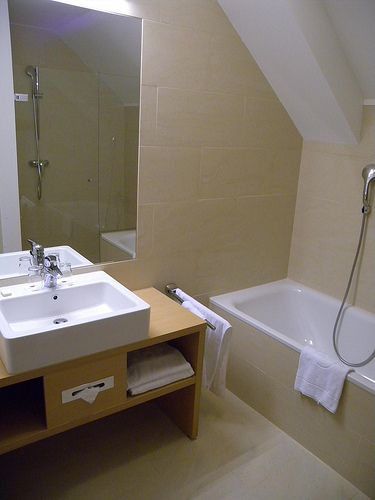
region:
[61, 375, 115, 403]
Built in tissue holder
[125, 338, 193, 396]
Two folded white towels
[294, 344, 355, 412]
White floor towel hanging off a bathtub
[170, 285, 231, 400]
Two towels hanging on a drying rack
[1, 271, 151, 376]
Raised white rectangle sink basin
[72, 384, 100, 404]
White tissue sticking out of a tissue holder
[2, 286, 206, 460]
Light wood bathroom table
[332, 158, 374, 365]
Long silver shower nozzle and handle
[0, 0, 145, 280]
Large bathroom mirror mounted in the wall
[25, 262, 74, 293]
Two glass cups on a sink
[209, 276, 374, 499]
white porcelain bath tub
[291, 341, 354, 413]
white bath mat draped over side of tub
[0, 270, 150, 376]
white rectangular bath sink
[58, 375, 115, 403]
silver tissue dispenser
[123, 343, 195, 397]
folded white towels on shelf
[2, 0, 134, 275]
mirror mounted on wall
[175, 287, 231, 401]
white towels on towel rack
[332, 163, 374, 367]
hand held shower nozzle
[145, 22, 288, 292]
beige tiles on wall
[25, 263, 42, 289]
drinking glass on sink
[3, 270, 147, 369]
empty white bathroom sink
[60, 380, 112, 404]
tissue dispenser with tissue hanging out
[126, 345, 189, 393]
white folded towels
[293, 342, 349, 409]
white towel hanging over bathtub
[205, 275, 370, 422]
empty clean white bathtub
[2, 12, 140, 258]
bathroom mirror mounted on wall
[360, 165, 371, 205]
shower head hanging on wall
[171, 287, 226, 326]
towel rack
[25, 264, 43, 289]
upside down glass cup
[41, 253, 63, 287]
silver sink faucet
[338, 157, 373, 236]
Shower head on wall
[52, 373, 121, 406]
Tissue box in counter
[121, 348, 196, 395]
White towels on shelf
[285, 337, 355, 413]
Towel hanging over edge of tub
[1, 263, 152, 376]
Square white sink on counter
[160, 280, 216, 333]
Towel rack on wall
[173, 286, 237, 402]
Towels hanging on rack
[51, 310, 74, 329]
Silver drain in sink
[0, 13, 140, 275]
Large mirror on wall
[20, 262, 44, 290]
Glass next to faucet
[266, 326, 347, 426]
The towel is on the side of the tub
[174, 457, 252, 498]
The floor is light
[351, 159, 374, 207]
The shower head is metal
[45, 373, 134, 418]
Tissues are in the cabinet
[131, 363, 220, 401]
The towels are folded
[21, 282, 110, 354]
The sink is empty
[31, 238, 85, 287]
The faucet is off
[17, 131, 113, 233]
The mirror is clean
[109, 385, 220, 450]
The cabinet is wooden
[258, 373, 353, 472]
The tub is tiled